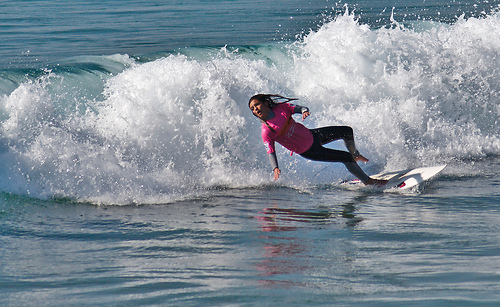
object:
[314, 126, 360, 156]
leg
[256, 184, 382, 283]
shadow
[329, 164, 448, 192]
surfboard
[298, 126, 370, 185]
pants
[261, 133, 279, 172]
arm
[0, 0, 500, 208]
wave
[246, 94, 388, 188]
surfer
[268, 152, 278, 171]
band